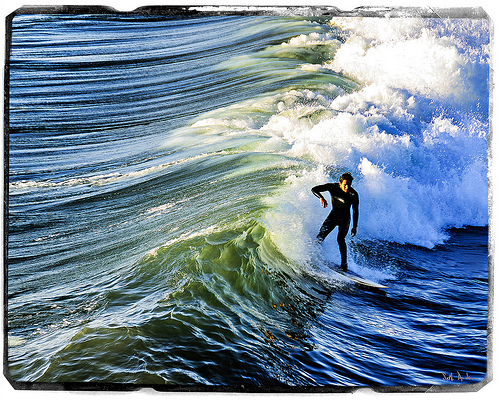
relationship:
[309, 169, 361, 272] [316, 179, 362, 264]
man in wetsuit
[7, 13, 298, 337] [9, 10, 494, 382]
lines in ocean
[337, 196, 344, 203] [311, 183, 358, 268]
logo on wetsuit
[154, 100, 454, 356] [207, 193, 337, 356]
ocean has colors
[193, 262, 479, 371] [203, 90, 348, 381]
streaks in waves